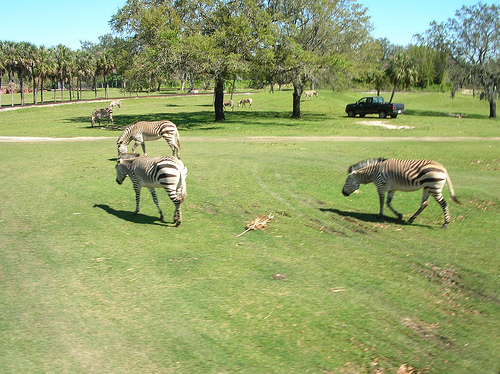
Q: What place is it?
A: It is a field.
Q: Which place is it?
A: It is a field.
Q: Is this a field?
A: Yes, it is a field.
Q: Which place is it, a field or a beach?
A: It is a field.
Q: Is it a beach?
A: No, it is a field.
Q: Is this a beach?
A: No, it is a field.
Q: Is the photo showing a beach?
A: No, the picture is showing a field.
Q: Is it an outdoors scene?
A: Yes, it is outdoors.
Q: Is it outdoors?
A: Yes, it is outdoors.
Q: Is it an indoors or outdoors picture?
A: It is outdoors.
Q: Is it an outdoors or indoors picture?
A: It is outdoors.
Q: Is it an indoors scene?
A: No, it is outdoors.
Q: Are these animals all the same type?
A: Yes, all the animals are zebras.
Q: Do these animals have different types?
A: No, all the animals are zebras.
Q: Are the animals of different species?
A: No, all the animals are zebras.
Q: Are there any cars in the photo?
A: No, there are no cars.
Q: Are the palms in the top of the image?
A: Yes, the palms are in the top of the image.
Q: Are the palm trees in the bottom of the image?
A: No, the palm trees are in the top of the image.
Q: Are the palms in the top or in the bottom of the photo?
A: The palms are in the top of the image.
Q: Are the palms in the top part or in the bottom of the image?
A: The palms are in the top of the image.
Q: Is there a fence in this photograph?
A: No, there are no fences.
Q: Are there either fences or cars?
A: No, there are no fences or cars.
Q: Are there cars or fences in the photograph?
A: No, there are no fences or cars.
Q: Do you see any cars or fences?
A: No, there are no fences or cars.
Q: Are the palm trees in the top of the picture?
A: Yes, the palm trees are in the top of the image.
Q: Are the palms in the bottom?
A: No, the palms are in the top of the image.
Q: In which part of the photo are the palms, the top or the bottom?
A: The palms are in the top of the image.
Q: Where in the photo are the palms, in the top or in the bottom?
A: The palms are in the top of the image.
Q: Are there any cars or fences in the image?
A: No, there are no cars or fences.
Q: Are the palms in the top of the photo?
A: Yes, the palms are in the top of the image.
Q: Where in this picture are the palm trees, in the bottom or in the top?
A: The palm trees are in the top of the image.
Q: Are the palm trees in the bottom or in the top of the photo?
A: The palm trees are in the top of the image.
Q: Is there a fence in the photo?
A: No, there are no fences.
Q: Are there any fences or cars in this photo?
A: No, there are no fences or cars.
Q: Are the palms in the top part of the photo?
A: Yes, the palms are in the top of the image.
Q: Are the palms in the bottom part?
A: No, the palms are in the top of the image.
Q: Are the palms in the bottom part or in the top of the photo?
A: The palms are in the top of the image.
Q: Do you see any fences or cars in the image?
A: No, there are no cars or fences.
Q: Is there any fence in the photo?
A: No, there are no fences.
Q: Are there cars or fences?
A: No, there are no fences or cars.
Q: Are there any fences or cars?
A: No, there are no fences or cars.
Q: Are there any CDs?
A: No, there are no cds.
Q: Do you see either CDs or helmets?
A: No, there are no CDs or helmets.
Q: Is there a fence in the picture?
A: No, there are no fences.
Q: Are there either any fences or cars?
A: No, there are no fences or cars.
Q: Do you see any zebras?
A: Yes, there is a zebra.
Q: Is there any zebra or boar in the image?
A: Yes, there is a zebra.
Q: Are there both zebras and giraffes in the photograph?
A: No, there is a zebra but no giraffes.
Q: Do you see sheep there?
A: No, there are no sheep.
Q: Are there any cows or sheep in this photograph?
A: No, there are no sheep or cows.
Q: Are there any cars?
A: No, there are no cars.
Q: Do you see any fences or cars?
A: No, there are no cars or fences.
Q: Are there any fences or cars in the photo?
A: No, there are no cars or fences.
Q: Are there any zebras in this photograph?
A: Yes, there is a zebra.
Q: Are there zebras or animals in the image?
A: Yes, there is a zebra.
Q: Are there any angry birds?
A: No, there are no angry birds.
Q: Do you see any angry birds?
A: No, there are no angry birds.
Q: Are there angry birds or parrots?
A: No, there are no angry birds or parrots.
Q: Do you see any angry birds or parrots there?
A: No, there are no angry birds or parrots.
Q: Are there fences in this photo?
A: No, there are no fences.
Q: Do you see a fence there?
A: No, there are no fences.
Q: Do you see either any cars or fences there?
A: No, there are no fences or cars.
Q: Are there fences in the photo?
A: No, there are no fences.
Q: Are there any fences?
A: No, there are no fences.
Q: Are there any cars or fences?
A: No, there are no fences or cars.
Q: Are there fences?
A: No, there are no fences.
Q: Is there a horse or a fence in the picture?
A: No, there are no fences or horses.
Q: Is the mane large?
A: Yes, the mane is large.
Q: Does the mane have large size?
A: Yes, the mane is large.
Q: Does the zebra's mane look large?
A: Yes, the mane is large.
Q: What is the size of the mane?
A: The mane is large.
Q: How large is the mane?
A: The mane is large.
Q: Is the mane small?
A: No, the mane is large.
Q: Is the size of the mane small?
A: No, the mane is large.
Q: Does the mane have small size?
A: No, the mane is large.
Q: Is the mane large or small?
A: The mane is large.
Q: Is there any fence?
A: No, there are no fences.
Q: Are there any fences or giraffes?
A: No, there are no fences or giraffes.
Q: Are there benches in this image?
A: No, there are no benches.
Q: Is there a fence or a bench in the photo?
A: No, there are no benches or fences.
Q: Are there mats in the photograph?
A: No, there are no mats.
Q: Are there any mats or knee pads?
A: No, there are no mats or knee pads.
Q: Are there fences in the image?
A: No, there are no fences.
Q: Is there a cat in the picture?
A: No, there are no cats.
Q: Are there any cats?
A: No, there are no cats.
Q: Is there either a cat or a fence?
A: No, there are no cats or fences.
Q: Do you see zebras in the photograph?
A: Yes, there is a zebra.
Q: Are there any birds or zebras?
A: Yes, there is a zebra.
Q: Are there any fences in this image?
A: No, there are no fences.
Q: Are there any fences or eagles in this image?
A: No, there are no fences or eagles.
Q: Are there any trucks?
A: Yes, there is a truck.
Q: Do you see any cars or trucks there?
A: Yes, there is a truck.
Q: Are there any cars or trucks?
A: Yes, there is a truck.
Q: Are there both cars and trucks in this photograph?
A: No, there is a truck but no cars.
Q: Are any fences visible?
A: No, there are no fences.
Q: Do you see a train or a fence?
A: No, there are no fences or trains.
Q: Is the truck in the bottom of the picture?
A: No, the truck is in the top of the image.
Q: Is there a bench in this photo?
A: No, there are no benches.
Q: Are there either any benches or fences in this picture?
A: No, there are no benches or fences.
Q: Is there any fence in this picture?
A: No, there are no fences.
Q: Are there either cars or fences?
A: No, there are no fences or cars.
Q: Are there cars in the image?
A: No, there are no cars.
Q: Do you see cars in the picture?
A: No, there are no cars.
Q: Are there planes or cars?
A: No, there are no cars or planes.